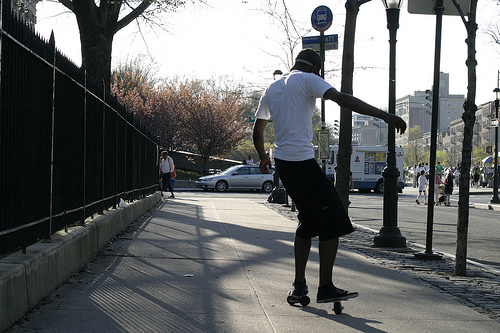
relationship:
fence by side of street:
[28, 12, 200, 249] [330, 189, 497, 270]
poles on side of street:
[425, 2, 444, 253] [330, 186, 497, 270]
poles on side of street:
[414, 25, 436, 282] [330, 186, 497, 270]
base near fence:
[6, 185, 166, 320] [6, 6, 166, 248]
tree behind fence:
[53, 0, 192, 105] [1, 3, 166, 270]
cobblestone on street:
[363, 229, 498, 322] [350, 190, 499, 272]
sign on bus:
[305, 3, 334, 36] [313, 8, 328, 22]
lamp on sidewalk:
[370, 0, 412, 262] [16, 196, 482, 318]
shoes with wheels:
[315, 284, 359, 302] [333, 300, 345, 315]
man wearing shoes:
[229, 52, 407, 283] [315, 284, 359, 302]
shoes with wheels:
[311, 280, 361, 303] [298, 298, 347, 310]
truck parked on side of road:
[319, 140, 404, 192] [339, 181, 498, 268]